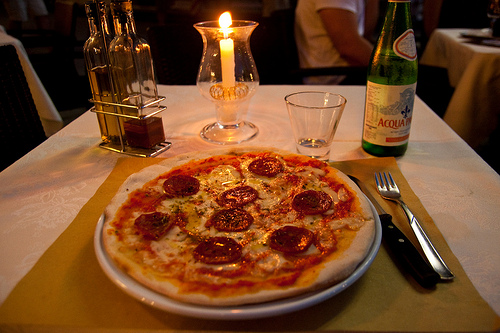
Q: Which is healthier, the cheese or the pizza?
A: The cheese is healthier than the pizza.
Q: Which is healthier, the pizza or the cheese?
A: The cheese is healthier than the pizza.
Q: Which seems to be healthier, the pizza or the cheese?
A: The cheese is healthier than the pizza.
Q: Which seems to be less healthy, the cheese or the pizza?
A: The pizza is less healthy than the cheese.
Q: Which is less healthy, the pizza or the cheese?
A: The pizza is less healthy than the cheese.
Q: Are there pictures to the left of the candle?
A: No, there is a container to the left of the candle.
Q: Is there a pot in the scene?
A: No, there are no pots.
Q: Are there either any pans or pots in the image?
A: No, there are no pots or pans.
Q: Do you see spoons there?
A: No, there are no spoons.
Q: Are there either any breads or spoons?
A: No, there are no spoons or breads.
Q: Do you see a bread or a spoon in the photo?
A: No, there are no spoons or breads.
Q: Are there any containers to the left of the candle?
A: Yes, there is a container to the left of the candle.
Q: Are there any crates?
A: No, there are no crates.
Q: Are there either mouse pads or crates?
A: No, there are no crates or mouse pads.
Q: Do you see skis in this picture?
A: No, there are no skis.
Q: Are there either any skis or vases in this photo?
A: No, there are no skis or vases.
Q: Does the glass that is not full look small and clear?
A: Yes, the glass is small and clear.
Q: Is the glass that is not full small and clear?
A: Yes, the glass is small and clear.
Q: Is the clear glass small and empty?
A: Yes, the glass is small and empty.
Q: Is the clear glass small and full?
A: No, the glass is small but empty.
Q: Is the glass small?
A: Yes, the glass is small.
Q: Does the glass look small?
A: Yes, the glass is small.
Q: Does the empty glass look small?
A: Yes, the glass is small.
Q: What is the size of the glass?
A: The glass is small.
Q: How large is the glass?
A: The glass is small.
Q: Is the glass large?
A: No, the glass is small.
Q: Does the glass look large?
A: No, the glass is small.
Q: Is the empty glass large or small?
A: The glass is small.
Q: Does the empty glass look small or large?
A: The glass is small.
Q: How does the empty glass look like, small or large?
A: The glass is small.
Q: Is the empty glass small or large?
A: The glass is small.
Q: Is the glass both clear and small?
A: Yes, the glass is clear and small.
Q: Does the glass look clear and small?
A: Yes, the glass is clear and small.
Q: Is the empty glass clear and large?
A: No, the glass is clear but small.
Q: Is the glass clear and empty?
A: Yes, the glass is clear and empty.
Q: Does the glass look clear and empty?
A: Yes, the glass is clear and empty.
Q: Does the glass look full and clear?
A: No, the glass is clear but empty.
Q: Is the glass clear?
A: Yes, the glass is clear.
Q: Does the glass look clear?
A: Yes, the glass is clear.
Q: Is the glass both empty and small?
A: Yes, the glass is empty and small.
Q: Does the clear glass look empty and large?
A: No, the glass is empty but small.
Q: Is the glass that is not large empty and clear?
A: Yes, the glass is empty and clear.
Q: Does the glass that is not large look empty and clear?
A: Yes, the glass is empty and clear.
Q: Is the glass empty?
A: Yes, the glass is empty.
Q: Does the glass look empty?
A: Yes, the glass is empty.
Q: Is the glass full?
A: No, the glass is empty.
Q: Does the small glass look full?
A: No, the glass is empty.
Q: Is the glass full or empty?
A: The glass is empty.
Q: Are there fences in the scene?
A: No, there are no fences.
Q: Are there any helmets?
A: No, there are no helmets.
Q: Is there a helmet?
A: No, there are no helmets.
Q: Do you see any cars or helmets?
A: No, there are no helmets or cars.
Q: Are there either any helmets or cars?
A: No, there are no helmets or cars.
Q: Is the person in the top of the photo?
A: Yes, the person is in the top of the image.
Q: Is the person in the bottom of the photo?
A: No, the person is in the top of the image.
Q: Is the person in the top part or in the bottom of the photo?
A: The person is in the top of the image.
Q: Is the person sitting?
A: Yes, the person is sitting.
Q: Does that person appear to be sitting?
A: Yes, the person is sitting.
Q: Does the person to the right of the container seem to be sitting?
A: Yes, the person is sitting.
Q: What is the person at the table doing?
A: The person is sitting.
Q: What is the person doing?
A: The person is sitting.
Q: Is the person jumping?
A: No, the person is sitting.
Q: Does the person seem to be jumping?
A: No, the person is sitting.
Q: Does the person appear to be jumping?
A: No, the person is sitting.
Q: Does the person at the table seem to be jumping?
A: No, the person is sitting.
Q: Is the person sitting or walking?
A: The person is sitting.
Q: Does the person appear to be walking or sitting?
A: The person is sitting.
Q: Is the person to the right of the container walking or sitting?
A: The person is sitting.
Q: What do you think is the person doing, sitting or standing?
A: The person is sitting.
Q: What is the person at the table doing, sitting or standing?
A: The person is sitting.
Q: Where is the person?
A: The person is at the table.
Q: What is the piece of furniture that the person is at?
A: The piece of furniture is a table.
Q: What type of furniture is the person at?
A: The person is at the table.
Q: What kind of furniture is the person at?
A: The person is at the table.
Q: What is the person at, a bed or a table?
A: The person is at a table.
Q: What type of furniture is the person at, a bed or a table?
A: The person is at a table.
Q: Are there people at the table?
A: Yes, there is a person at the table.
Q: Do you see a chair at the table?
A: No, there is a person at the table.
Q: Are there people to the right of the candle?
A: Yes, there is a person to the right of the candle.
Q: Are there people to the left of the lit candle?
A: No, the person is to the right of the candle.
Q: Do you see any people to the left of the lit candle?
A: No, the person is to the right of the candle.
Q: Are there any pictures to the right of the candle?
A: No, there is a person to the right of the candle.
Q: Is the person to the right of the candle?
A: Yes, the person is to the right of the candle.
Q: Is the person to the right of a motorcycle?
A: No, the person is to the right of the candle.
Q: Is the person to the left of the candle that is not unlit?
A: No, the person is to the right of the candle.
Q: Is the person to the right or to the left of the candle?
A: The person is to the right of the candle.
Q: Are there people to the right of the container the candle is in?
A: Yes, there is a person to the right of the container.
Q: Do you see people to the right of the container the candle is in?
A: Yes, there is a person to the right of the container.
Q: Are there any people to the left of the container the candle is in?
A: No, the person is to the right of the container.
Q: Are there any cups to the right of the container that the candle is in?
A: No, there is a person to the right of the container.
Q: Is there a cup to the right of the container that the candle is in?
A: No, there is a person to the right of the container.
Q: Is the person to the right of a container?
A: Yes, the person is to the right of a container.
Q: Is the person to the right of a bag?
A: No, the person is to the right of a container.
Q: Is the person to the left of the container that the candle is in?
A: No, the person is to the right of the container.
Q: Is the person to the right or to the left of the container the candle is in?
A: The person is to the right of the container.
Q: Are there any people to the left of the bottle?
A: Yes, there is a person to the left of the bottle.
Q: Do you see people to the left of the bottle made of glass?
A: Yes, there is a person to the left of the bottle.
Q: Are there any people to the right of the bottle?
A: No, the person is to the left of the bottle.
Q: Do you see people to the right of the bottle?
A: No, the person is to the left of the bottle.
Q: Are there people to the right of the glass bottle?
A: No, the person is to the left of the bottle.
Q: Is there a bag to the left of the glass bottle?
A: No, there is a person to the left of the bottle.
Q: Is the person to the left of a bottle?
A: Yes, the person is to the left of a bottle.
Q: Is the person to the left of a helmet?
A: No, the person is to the left of a bottle.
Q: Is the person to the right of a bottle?
A: No, the person is to the left of a bottle.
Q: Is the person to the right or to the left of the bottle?
A: The person is to the left of the bottle.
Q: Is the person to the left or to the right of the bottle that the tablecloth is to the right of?
A: The person is to the left of the bottle.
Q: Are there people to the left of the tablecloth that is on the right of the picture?
A: Yes, there is a person to the left of the tablecloth.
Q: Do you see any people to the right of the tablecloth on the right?
A: No, the person is to the left of the tablecloth.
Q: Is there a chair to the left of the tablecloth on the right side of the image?
A: No, there is a person to the left of the tablecloth.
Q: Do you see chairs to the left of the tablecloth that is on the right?
A: No, there is a person to the left of the tablecloth.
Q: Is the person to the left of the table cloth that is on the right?
A: Yes, the person is to the left of the tablecloth.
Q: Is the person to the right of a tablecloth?
A: No, the person is to the left of a tablecloth.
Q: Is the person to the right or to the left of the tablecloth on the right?
A: The person is to the left of the table cloth.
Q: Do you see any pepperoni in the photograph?
A: Yes, there is pepperoni.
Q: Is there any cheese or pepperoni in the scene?
A: Yes, there is pepperoni.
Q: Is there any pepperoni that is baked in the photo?
A: Yes, there is baked pepperoni.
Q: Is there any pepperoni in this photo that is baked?
A: Yes, there is pepperoni that is baked.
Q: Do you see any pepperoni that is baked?
A: Yes, there is pepperoni that is baked.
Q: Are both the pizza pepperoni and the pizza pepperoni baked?
A: Yes, both the pepperoni and the pepperoni are baked.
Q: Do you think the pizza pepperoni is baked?
A: Yes, the pepperoni is baked.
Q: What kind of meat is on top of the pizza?
A: The meat is pepperoni.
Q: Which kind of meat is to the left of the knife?
A: The meat is pepperoni.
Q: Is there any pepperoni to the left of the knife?
A: Yes, there is pepperoni to the left of the knife.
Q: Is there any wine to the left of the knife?
A: No, there is pepperoni to the left of the knife.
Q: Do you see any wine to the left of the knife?
A: No, there is pepperoni to the left of the knife.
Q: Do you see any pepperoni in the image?
A: Yes, there is pepperoni.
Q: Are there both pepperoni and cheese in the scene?
A: Yes, there are both pepperoni and cheese.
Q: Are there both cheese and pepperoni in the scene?
A: Yes, there are both pepperoni and cheese.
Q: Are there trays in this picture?
A: No, there are no trays.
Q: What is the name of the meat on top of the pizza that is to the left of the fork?
A: The meat is pepperoni.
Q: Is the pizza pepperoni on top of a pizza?
A: Yes, the pepperoni is on top of a pizza.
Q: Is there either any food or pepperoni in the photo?
A: Yes, there is pepperoni.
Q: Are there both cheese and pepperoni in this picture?
A: Yes, there are both pepperoni and cheese.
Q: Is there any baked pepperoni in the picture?
A: Yes, there is baked pepperoni.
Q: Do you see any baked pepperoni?
A: Yes, there is baked pepperoni.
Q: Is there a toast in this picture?
A: No, there are no toasts.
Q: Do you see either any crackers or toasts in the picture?
A: No, there are no toasts or crackers.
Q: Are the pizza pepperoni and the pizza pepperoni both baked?
A: Yes, both the pepperoni and the pepperoni are baked.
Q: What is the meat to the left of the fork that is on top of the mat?
A: The meat is pepperoni.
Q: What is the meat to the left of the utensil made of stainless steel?
A: The meat is pepperoni.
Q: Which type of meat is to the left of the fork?
A: The meat is pepperoni.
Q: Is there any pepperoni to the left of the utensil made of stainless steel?
A: Yes, there is pepperoni to the left of the fork.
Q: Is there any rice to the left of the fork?
A: No, there is pepperoni to the left of the fork.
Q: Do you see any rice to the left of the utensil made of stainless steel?
A: No, there is pepperoni to the left of the fork.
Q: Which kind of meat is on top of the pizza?
A: The meat is pepperoni.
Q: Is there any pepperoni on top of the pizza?
A: Yes, there is pepperoni on top of the pizza.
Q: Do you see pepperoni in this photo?
A: Yes, there is pepperoni.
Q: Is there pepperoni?
A: Yes, there is pepperoni.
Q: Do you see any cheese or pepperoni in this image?
A: Yes, there is pepperoni.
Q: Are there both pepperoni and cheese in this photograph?
A: Yes, there are both pepperoni and cheese.